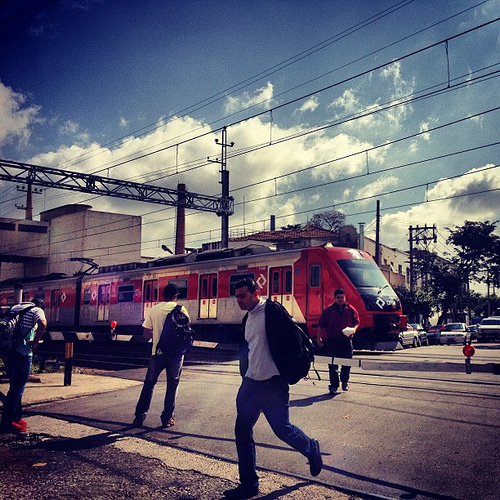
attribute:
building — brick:
[201, 222, 453, 294]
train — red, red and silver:
[1, 230, 410, 352]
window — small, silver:
[92, 280, 133, 301]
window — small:
[336, 256, 396, 293]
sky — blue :
[3, 6, 498, 297]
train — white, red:
[4, 250, 477, 360]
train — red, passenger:
[8, 234, 413, 366]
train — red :
[31, 231, 376, 352]